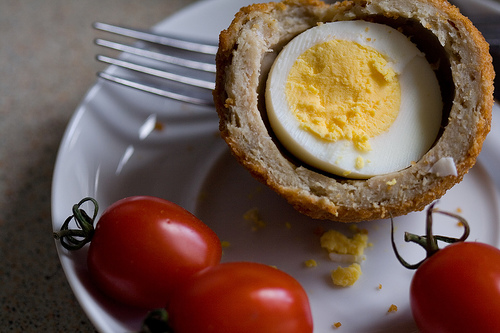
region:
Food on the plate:
[90, 37, 493, 297]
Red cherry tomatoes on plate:
[77, 194, 284, 329]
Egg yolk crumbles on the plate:
[282, 222, 395, 295]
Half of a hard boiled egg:
[268, 30, 444, 162]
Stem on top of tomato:
[369, 186, 483, 292]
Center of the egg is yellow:
[290, 41, 430, 146]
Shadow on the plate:
[80, 68, 177, 143]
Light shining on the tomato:
[240, 270, 312, 328]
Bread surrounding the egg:
[206, 60, 266, 149]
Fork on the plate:
[78, 10, 232, 112]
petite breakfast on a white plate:
[49, 0, 499, 330]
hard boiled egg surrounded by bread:
[213, 2, 494, 221]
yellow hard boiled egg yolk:
[285, 38, 400, 168]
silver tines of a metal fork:
[92, 21, 217, 111]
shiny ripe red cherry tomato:
[55, 195, 219, 310]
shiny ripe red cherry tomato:
[144, 259, 312, 331]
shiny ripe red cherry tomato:
[387, 203, 498, 330]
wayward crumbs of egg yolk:
[220, 206, 367, 288]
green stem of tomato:
[51, 196, 98, 252]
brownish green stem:
[390, 200, 469, 270]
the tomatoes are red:
[72, 179, 243, 301]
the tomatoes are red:
[176, 235, 307, 328]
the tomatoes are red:
[396, 230, 483, 329]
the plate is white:
[46, 67, 323, 297]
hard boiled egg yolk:
[285, 38, 400, 139]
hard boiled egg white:
[264, 18, 438, 179]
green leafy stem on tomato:
[54, 195, 96, 252]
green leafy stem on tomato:
[386, 204, 470, 267]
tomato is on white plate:
[86, 195, 223, 314]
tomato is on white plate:
[169, 261, 313, 331]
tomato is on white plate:
[411, 242, 496, 330]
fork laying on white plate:
[95, 20, 219, 104]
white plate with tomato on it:
[54, 0, 498, 331]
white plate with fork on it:
[51, 3, 497, 328]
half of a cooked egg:
[265, 20, 442, 171]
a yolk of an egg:
[323, 230, 375, 277]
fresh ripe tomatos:
[60, 194, 310, 331]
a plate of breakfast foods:
[55, 2, 494, 328]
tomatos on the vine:
[387, 213, 499, 331]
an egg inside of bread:
[218, 2, 490, 219]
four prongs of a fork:
[90, 25, 215, 107]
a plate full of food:
[58, 4, 492, 319]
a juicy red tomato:
[166, 263, 307, 330]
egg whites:
[401, 52, 432, 139]